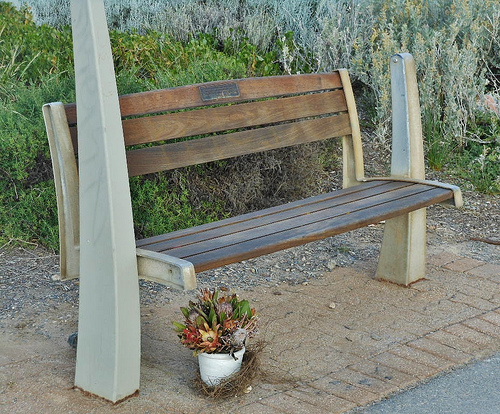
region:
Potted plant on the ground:
[174, 281, 283, 401]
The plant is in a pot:
[168, 275, 291, 402]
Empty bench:
[54, 13, 452, 403]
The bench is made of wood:
[35, 28, 461, 394]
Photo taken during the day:
[6, 10, 488, 388]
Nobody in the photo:
[11, 6, 493, 406]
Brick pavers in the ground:
[48, 257, 476, 397]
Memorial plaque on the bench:
[197, 70, 256, 107]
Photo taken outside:
[25, 0, 493, 409]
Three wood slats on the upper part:
[104, 75, 364, 152]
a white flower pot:
[175, 275, 278, 396]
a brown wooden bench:
[18, 65, 479, 347]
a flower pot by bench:
[141, 266, 295, 411]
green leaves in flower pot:
[185, 292, 258, 333]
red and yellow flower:
[187, 320, 229, 359]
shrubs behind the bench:
[4, 22, 323, 228]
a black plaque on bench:
[201, 82, 245, 102]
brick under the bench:
[13, 228, 486, 411]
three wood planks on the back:
[57, 72, 349, 174]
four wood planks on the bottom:
[141, 158, 448, 268]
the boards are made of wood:
[61, 60, 351, 175]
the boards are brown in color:
[60, 70, 355, 170]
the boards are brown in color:
[140, 175, 450, 270]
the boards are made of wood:
[127, 178, 448, 273]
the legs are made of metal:
[63, 15, 434, 388]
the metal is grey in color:
[72, 30, 429, 393]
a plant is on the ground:
[182, 284, 257, 355]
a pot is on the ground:
[196, 349, 250, 389]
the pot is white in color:
[198, 348, 243, 387]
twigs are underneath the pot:
[191, 347, 268, 403]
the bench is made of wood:
[39, 103, 446, 305]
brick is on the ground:
[287, 309, 407, 391]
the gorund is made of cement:
[415, 383, 498, 408]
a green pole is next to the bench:
[49, 32, 186, 387]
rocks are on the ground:
[245, 262, 371, 281]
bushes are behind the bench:
[113, 23, 238, 154]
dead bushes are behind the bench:
[347, 13, 484, 134]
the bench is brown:
[174, 90, 497, 279]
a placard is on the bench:
[172, 85, 331, 120]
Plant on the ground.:
[171, 283, 271, 395]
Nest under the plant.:
[190, 360, 268, 400]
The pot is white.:
[195, 347, 245, 379]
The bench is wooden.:
[51, 70, 428, 263]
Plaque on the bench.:
[186, 77, 247, 104]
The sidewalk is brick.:
[0, 247, 493, 399]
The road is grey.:
[379, 355, 497, 412]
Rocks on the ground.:
[236, 240, 351, 308]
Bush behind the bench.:
[3, 34, 269, 195]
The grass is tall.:
[283, 11, 498, 126]